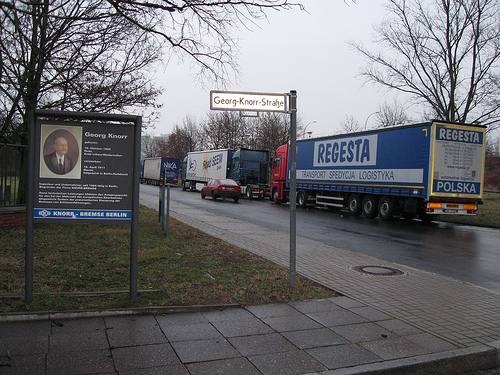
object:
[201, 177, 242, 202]
car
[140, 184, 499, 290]
street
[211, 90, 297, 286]
sign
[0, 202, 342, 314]
grass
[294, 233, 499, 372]
corner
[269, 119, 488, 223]
trailer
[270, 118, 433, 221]
semi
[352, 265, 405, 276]
man hole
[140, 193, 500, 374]
sidewalk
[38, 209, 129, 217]
sign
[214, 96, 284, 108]
lettering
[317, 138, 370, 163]
lettering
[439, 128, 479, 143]
lettering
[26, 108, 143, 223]
sign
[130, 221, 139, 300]
pole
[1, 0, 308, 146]
tree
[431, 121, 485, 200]
door edge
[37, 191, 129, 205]
words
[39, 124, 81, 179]
picture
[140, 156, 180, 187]
semi